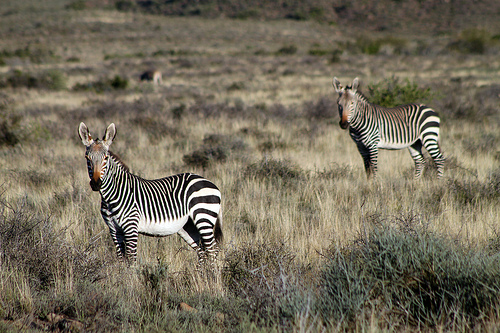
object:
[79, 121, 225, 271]
zebra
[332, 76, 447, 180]
zebra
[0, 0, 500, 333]
grass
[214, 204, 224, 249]
tail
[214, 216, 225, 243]
hair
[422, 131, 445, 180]
leg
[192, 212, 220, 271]
leg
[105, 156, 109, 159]
eye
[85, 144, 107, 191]
face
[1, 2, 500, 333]
field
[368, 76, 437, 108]
shrub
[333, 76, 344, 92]
ear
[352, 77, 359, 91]
ear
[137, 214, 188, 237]
belly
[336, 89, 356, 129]
face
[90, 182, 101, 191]
nose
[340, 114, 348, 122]
brown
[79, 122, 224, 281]
stripe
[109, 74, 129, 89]
bush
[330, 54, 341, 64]
bush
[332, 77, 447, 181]
stripe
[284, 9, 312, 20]
shrub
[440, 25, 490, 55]
shrub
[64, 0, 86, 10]
shrub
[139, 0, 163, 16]
shrub